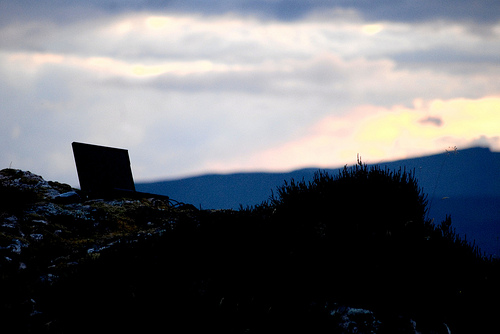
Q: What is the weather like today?
A: It is cloudy.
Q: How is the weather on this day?
A: It is cloudy.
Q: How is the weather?
A: It is cloudy.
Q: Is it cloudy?
A: Yes, it is cloudy.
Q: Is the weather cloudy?
A: Yes, it is cloudy.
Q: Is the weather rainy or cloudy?
A: It is cloudy.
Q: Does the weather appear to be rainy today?
A: No, it is cloudy.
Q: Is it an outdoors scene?
A: Yes, it is outdoors.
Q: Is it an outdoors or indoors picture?
A: It is outdoors.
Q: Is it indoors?
A: No, it is outdoors.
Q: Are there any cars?
A: No, there are no cars.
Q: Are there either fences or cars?
A: No, there are no cars or fences.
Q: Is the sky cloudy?
A: Yes, the sky is cloudy.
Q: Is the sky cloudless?
A: No, the sky is cloudy.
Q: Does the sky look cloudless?
A: No, the sky is cloudy.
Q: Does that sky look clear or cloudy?
A: The sky is cloudy.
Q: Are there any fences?
A: No, there are no fences.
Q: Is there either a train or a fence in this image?
A: No, there are no fences or trains.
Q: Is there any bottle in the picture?
A: No, there are no bottles.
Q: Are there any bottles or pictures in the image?
A: No, there are no bottles or pictures.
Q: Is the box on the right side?
A: No, the box is on the left of the image.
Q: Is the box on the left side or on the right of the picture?
A: The box is on the left of the image.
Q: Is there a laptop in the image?
A: Yes, there is a laptop.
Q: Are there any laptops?
A: Yes, there is a laptop.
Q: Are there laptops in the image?
A: Yes, there is a laptop.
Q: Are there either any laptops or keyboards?
A: Yes, there is a laptop.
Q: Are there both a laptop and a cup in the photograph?
A: No, there is a laptop but no cups.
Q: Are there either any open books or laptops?
A: Yes, there is an open laptop.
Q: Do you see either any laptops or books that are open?
A: Yes, the laptop is open.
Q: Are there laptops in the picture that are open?
A: Yes, there is an open laptop.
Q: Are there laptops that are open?
A: Yes, there is a laptop that is open.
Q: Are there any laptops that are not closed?
A: Yes, there is a open laptop.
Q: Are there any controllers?
A: No, there are no controllers.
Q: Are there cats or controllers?
A: No, there are no controllers or cats.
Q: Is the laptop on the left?
A: Yes, the laptop is on the left of the image.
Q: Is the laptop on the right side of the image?
A: No, the laptop is on the left of the image.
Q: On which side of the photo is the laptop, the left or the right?
A: The laptop is on the left of the image.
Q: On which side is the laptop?
A: The laptop is on the left of the image.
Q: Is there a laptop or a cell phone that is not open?
A: No, there is a laptop but it is open.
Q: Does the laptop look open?
A: Yes, the laptop is open.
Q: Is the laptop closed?
A: No, the laptop is open.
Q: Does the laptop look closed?
A: No, the laptop is open.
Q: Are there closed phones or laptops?
A: No, there is a laptop but it is open.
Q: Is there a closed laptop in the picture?
A: No, there is a laptop but it is open.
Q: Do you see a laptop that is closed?
A: No, there is a laptop but it is open.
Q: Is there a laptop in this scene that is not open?
A: No, there is a laptop but it is open.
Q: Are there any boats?
A: No, there are no boats.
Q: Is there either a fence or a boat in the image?
A: No, there are no boats or fences.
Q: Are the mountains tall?
A: Yes, the mountains are tall.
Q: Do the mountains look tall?
A: Yes, the mountains are tall.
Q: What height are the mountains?
A: The mountains are tall.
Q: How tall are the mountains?
A: The mountains are tall.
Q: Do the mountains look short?
A: No, the mountains are tall.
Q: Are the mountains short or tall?
A: The mountains are tall.